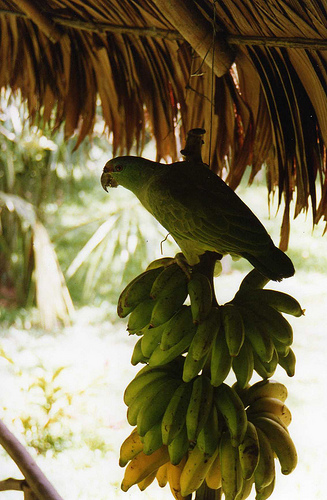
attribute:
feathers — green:
[148, 162, 298, 284]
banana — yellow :
[120, 445, 170, 491]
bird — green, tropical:
[114, 155, 280, 253]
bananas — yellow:
[114, 388, 294, 498]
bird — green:
[99, 152, 297, 278]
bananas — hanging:
[116, 240, 303, 499]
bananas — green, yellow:
[116, 249, 308, 391]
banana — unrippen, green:
[184, 268, 222, 323]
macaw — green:
[94, 154, 299, 289]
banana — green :
[240, 288, 307, 322]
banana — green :
[185, 377, 215, 444]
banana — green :
[141, 380, 171, 431]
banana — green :
[107, 260, 149, 313]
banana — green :
[255, 415, 298, 474]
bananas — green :
[97, 253, 310, 497]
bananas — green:
[136, 284, 285, 445]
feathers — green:
[140, 175, 297, 277]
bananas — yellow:
[118, 320, 261, 490]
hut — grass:
[1, 1, 316, 254]